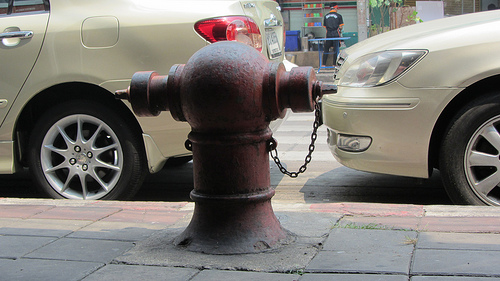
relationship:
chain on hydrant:
[253, 98, 326, 181] [113, 38, 340, 259]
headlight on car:
[338, 47, 430, 89] [323, 8, 499, 203]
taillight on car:
[192, 14, 263, 55] [323, 8, 499, 203]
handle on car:
[0, 29, 35, 42] [323, 8, 499, 203]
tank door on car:
[79, 13, 122, 52] [323, 8, 499, 203]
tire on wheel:
[25, 96, 145, 201] [40, 113, 124, 197]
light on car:
[335, 131, 373, 154] [323, 8, 499, 203]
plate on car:
[265, 25, 285, 60] [0, 1, 287, 202]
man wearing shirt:
[322, 7, 344, 68] [323, 10, 344, 33]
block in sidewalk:
[317, 70, 333, 81] [320, 84, 341, 94]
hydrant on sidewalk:
[113, 38, 340, 259] [4, 213, 499, 281]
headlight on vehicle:
[338, 47, 430, 89] [323, 8, 499, 203]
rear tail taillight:
[235, 1, 300, 69] [192, 14, 263, 55]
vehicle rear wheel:
[0, 1, 287, 202] [40, 113, 124, 197]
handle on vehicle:
[0, 29, 35, 42] [0, 1, 287, 202]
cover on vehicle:
[79, 13, 122, 52] [0, 1, 287, 202]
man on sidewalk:
[323, 11, 345, 33] [320, 84, 341, 94]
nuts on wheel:
[69, 144, 94, 173] [40, 113, 124, 197]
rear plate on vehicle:
[235, 1, 300, 69] [0, 1, 287, 202]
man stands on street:
[323, 11, 345, 33] [313, 66, 339, 76]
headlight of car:
[338, 47, 430, 89] [323, 8, 499, 203]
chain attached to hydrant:
[253, 98, 326, 181] [113, 38, 340, 259]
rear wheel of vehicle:
[40, 113, 124, 197] [0, 1, 287, 202]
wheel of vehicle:
[463, 115, 500, 204] [323, 8, 499, 203]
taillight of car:
[192, 14, 263, 55] [0, 1, 287, 202]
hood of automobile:
[323, 9, 499, 90] [323, 8, 499, 203]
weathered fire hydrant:
[140, 36, 314, 236] [113, 38, 340, 259]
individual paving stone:
[24, 232, 133, 260] [25, 240, 117, 261]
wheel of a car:
[40, 113, 124, 197] [0, 1, 287, 202]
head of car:
[319, 25, 385, 179] [323, 8, 499, 203]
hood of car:
[323, 9, 499, 90] [323, 8, 499, 203]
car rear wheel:
[0, 1, 287, 202] [40, 113, 124, 197]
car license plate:
[0, 1, 287, 202] [265, 25, 285, 60]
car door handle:
[0, 1, 287, 202] [0, 29, 35, 40]